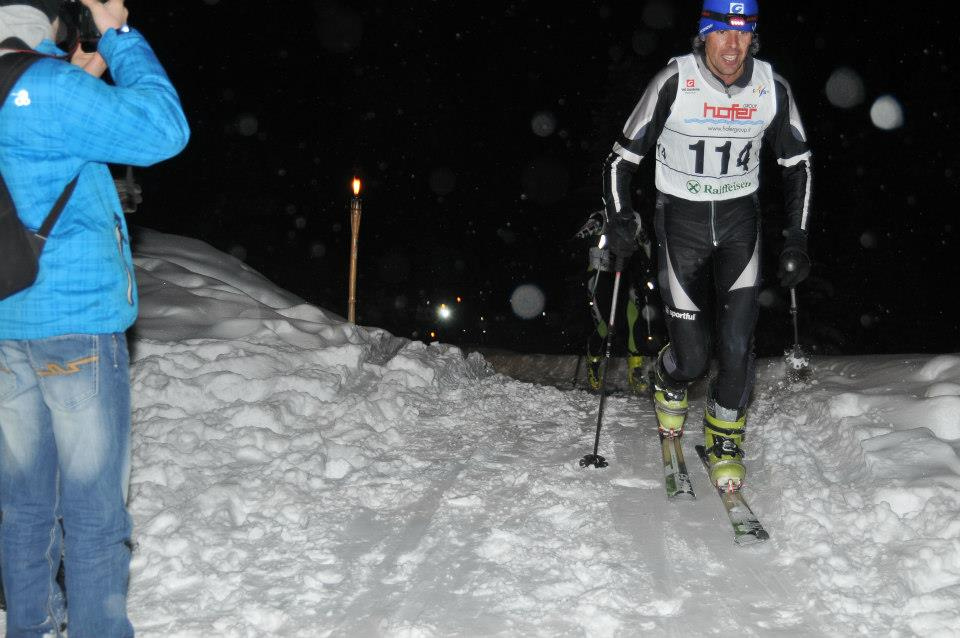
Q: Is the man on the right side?
A: Yes, the man is on the right of the image.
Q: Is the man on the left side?
A: No, the man is on the right of the image.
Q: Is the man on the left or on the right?
A: The man is on the right of the image.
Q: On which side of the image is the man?
A: The man is on the right of the image.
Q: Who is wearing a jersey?
A: The man is wearing a jersey.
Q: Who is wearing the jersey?
A: The man is wearing a jersey.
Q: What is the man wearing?
A: The man is wearing a jersey.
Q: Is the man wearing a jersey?
A: Yes, the man is wearing a jersey.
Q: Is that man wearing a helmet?
A: No, the man is wearing a jersey.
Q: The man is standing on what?
A: The man is standing on the ski.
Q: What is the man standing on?
A: The man is standing on the ski.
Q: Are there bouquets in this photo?
A: No, there are no bouquets.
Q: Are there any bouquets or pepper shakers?
A: No, there are no bouquets or pepper shakers.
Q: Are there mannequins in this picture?
A: No, there are no mannequins.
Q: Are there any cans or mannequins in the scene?
A: No, there are no mannequins or cans.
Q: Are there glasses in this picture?
A: No, there are no glasses.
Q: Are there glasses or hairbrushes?
A: No, there are no glasses or hairbrushes.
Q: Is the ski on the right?
A: Yes, the ski is on the right of the image.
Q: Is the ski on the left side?
A: No, the ski is on the right of the image.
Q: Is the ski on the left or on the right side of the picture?
A: The ski is on the right of the image.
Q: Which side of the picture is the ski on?
A: The ski is on the right of the image.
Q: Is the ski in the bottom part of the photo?
A: Yes, the ski is in the bottom of the image.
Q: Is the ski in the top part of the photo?
A: No, the ski is in the bottom of the image.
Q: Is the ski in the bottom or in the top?
A: The ski is in the bottom of the image.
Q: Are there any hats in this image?
A: Yes, there is a hat.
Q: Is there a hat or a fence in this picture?
A: Yes, there is a hat.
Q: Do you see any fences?
A: No, there are no fences.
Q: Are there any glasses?
A: No, there are no glasses.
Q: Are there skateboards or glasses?
A: No, there are no glasses or skateboards.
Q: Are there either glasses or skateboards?
A: No, there are no glasses or skateboards.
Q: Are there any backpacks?
A: Yes, there is a backpack.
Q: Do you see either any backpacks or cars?
A: Yes, there is a backpack.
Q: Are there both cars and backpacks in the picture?
A: No, there is a backpack but no cars.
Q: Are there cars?
A: No, there are no cars.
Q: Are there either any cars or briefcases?
A: No, there are no cars or briefcases.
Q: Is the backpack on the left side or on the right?
A: The backpack is on the left of the image.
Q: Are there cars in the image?
A: No, there are no cars.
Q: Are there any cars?
A: No, there are no cars.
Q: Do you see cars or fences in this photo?
A: No, there are no cars or fences.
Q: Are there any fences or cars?
A: No, there are no cars or fences.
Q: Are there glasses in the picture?
A: No, there are no glasses.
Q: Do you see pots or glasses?
A: No, there are no glasses or pots.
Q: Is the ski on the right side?
A: Yes, the ski is on the right of the image.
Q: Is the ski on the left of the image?
A: No, the ski is on the right of the image.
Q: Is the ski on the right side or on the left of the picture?
A: The ski is on the right of the image.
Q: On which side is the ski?
A: The ski is on the right of the image.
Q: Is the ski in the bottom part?
A: Yes, the ski is in the bottom of the image.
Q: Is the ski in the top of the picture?
A: No, the ski is in the bottom of the image.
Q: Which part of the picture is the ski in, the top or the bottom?
A: The ski is in the bottom of the image.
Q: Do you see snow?
A: Yes, there is snow.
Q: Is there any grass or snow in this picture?
A: Yes, there is snow.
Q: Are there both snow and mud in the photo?
A: No, there is snow but no mud.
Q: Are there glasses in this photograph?
A: No, there are no glasses.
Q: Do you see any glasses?
A: No, there are no glasses.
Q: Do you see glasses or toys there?
A: No, there are no glasses or toys.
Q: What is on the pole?
A: The snow is on the pole.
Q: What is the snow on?
A: The snow is on the pole.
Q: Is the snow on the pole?
A: Yes, the snow is on the pole.